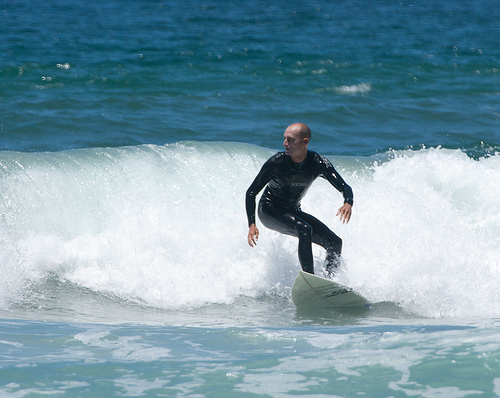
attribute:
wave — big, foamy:
[0, 144, 499, 336]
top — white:
[2, 130, 498, 184]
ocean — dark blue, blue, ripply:
[0, 3, 499, 397]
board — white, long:
[287, 266, 372, 319]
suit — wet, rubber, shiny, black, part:
[244, 152, 354, 283]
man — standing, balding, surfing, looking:
[242, 120, 356, 281]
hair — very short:
[282, 120, 313, 144]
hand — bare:
[337, 200, 357, 221]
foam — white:
[69, 309, 186, 370]